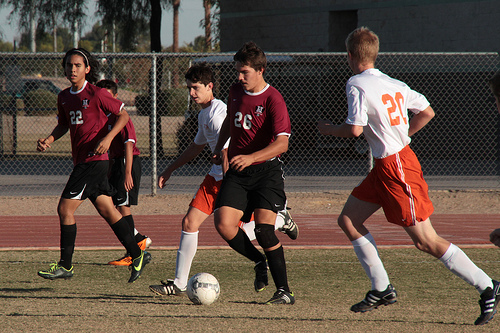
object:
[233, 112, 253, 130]
number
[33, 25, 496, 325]
group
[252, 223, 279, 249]
knee brace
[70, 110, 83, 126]
22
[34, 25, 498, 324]
four kids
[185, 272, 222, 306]
ball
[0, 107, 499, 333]
ground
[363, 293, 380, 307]
lines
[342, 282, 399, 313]
shoe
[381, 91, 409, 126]
number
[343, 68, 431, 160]
shirt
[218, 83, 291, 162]
shirt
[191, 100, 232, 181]
shirt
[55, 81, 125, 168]
shirt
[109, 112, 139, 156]
shirt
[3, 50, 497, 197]
fence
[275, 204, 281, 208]
logo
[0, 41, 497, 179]
shade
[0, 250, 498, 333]
field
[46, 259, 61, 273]
laces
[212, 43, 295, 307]
boy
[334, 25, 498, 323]
player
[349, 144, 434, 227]
shorts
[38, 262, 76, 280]
shoe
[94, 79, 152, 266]
player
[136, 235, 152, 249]
shoes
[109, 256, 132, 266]
shoes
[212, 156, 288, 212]
shorts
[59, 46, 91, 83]
head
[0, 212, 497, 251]
red track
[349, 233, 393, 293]
socks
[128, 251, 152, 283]
shoe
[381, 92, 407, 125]
orange number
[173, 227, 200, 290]
sock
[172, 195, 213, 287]
leg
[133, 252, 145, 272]
nike check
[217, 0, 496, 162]
building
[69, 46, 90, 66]
band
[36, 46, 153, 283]
boy